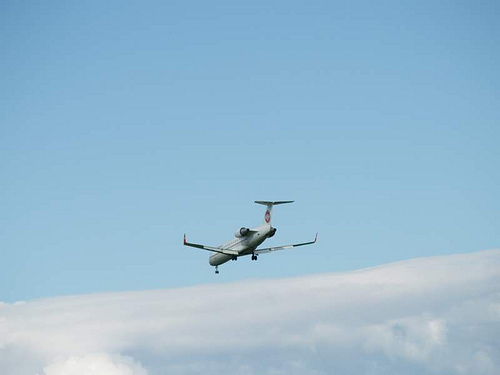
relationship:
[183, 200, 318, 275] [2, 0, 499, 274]
plane in air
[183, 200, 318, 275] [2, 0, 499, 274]
airplane in air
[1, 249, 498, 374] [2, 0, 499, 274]
cloud in sky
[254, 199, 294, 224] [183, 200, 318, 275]
tail on plane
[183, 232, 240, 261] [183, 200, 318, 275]
wing on plane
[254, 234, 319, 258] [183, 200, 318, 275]
wing on plane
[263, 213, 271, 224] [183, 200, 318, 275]
circle of plane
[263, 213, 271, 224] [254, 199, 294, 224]
circle on tail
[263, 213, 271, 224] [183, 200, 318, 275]
circle on plane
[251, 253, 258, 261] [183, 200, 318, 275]
wheel on plane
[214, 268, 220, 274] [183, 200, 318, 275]
wheel on plane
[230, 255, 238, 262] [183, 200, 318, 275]
wheel on plane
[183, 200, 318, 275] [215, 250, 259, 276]
plane landing gear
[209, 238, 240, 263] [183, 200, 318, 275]
windows of plane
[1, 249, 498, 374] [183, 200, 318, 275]
clouds under plane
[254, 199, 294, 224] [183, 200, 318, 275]
tail of jet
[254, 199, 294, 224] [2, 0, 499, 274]
tail in sky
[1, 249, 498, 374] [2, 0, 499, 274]
clouds in sky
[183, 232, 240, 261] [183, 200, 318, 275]
wing of jet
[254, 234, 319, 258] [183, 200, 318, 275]
wing of jet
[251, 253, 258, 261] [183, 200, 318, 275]
wheel of jet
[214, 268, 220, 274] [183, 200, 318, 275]
wheel of jet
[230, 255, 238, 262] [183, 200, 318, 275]
wheel of plane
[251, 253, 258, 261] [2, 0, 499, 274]
wheel in sky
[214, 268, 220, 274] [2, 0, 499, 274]
wheel in sky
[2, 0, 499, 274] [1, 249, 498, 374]
sky with cloud